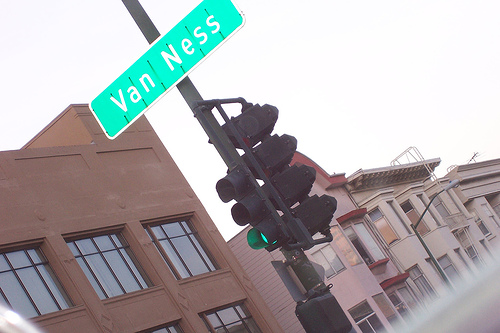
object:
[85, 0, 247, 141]
sign